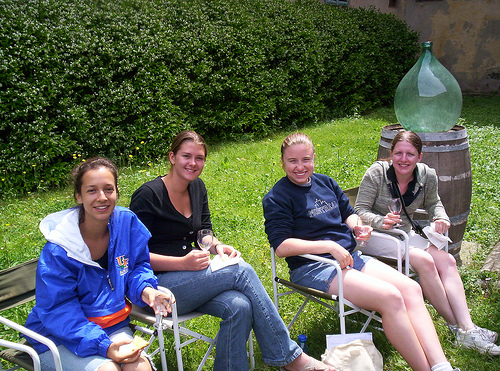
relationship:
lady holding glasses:
[261, 130, 449, 370] [104, 213, 429, 371]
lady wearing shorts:
[261, 130, 449, 370] [306, 231, 474, 351]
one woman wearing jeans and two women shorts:
[183, 253, 270, 317] [286, 247, 368, 295]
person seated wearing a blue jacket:
[16, 156, 176, 371] [54, 224, 166, 339]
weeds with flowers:
[225, 144, 277, 245] [228, 87, 268, 250]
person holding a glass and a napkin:
[356, 129, 499, 355] [414, 224, 459, 253]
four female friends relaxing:
[22, 129, 447, 352] [48, 233, 408, 371]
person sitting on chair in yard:
[43, 176, 193, 371] [14, 119, 366, 341]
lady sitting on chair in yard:
[261, 130, 449, 370] [73, 93, 434, 237]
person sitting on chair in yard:
[390, 98, 459, 224] [104, 215, 471, 371]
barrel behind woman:
[447, 123, 464, 202] [394, 178, 453, 283]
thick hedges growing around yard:
[23, 53, 223, 177] [40, 104, 397, 267]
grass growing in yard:
[7, 214, 34, 280] [57, 118, 469, 314]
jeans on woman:
[205, 248, 257, 339] [173, 179, 254, 362]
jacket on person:
[29, 198, 159, 332] [16, 156, 176, 371]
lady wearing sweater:
[261, 130, 449, 370] [260, 172, 359, 271]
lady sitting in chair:
[259, 130, 462, 370] [269, 230, 401, 336]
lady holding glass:
[129, 127, 338, 369] [195, 226, 213, 253]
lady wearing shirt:
[259, 130, 462, 370] [260, 169, 360, 269]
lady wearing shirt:
[129, 127, 338, 369] [128, 172, 216, 274]